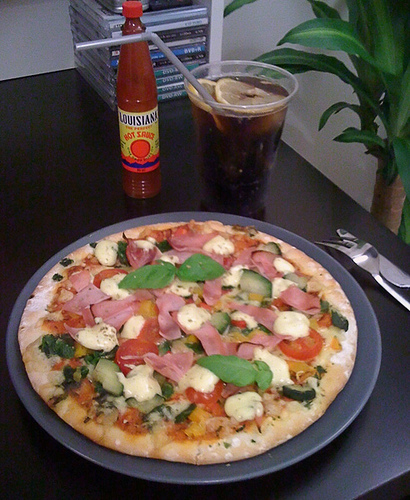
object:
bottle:
[118, 1, 163, 200]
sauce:
[120, 31, 158, 196]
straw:
[75, 31, 220, 116]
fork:
[313, 229, 410, 311]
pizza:
[19, 219, 359, 466]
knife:
[336, 226, 410, 289]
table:
[1, 71, 408, 500]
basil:
[195, 354, 273, 390]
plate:
[7, 213, 383, 486]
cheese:
[274, 311, 310, 339]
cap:
[121, 1, 144, 20]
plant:
[220, 2, 410, 244]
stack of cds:
[69, 0, 208, 110]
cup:
[183, 59, 299, 217]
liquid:
[189, 73, 289, 214]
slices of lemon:
[190, 76, 289, 113]